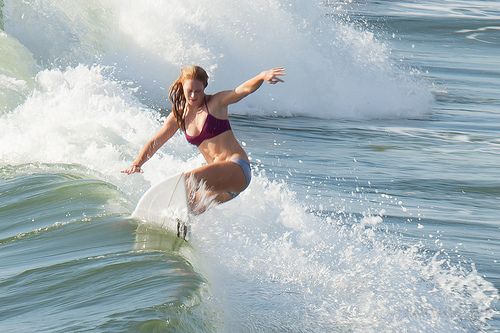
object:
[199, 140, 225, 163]
abs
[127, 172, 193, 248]
board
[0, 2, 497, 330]
ocean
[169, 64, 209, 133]
hair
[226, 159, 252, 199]
bottoms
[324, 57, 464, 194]
water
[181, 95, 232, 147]
bikini top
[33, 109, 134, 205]
water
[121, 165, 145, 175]
woman's hand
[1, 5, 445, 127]
ocean spray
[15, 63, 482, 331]
wave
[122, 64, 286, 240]
surfer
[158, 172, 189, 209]
tip